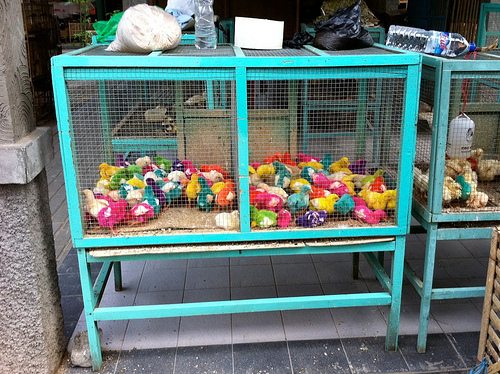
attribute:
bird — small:
[80, 182, 106, 218]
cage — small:
[47, 40, 422, 369]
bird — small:
[125, 186, 145, 202]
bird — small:
[130, 152, 153, 169]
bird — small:
[95, 199, 129, 236]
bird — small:
[123, 200, 153, 228]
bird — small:
[178, 156, 198, 173]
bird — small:
[349, 201, 389, 223]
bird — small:
[274, 208, 293, 228]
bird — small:
[260, 191, 285, 209]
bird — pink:
[95, 198, 127, 235]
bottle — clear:
[383, 23, 481, 63]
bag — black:
[309, 2, 373, 51]